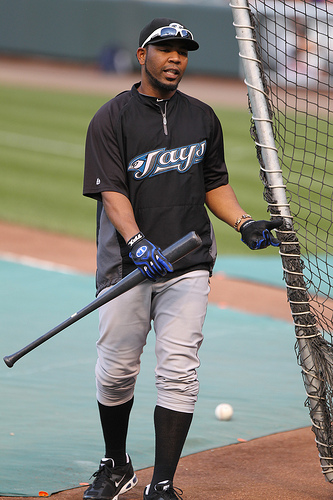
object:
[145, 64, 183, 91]
beard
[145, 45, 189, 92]
face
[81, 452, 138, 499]
shoes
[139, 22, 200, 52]
hat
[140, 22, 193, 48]
glasses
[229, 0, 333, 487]
pole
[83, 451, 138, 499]
cleats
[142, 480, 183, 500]
cleats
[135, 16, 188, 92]
head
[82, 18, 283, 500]
man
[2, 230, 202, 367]
baseball bat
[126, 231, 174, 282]
glove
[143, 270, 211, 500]
legs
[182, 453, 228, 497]
ground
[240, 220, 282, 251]
glove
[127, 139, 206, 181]
logo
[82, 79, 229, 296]
jersey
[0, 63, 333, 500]
field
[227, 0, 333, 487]
net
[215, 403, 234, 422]
baseball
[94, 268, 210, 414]
shorts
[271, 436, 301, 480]
ground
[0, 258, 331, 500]
tarp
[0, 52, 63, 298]
ground